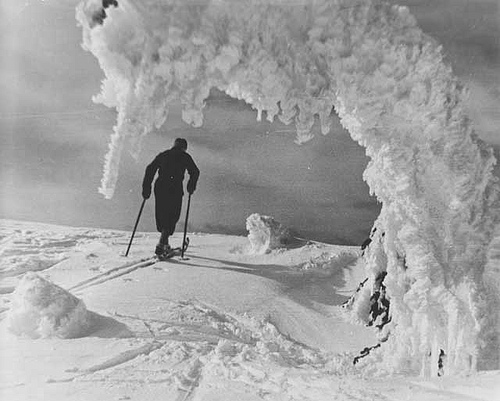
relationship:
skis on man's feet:
[153, 239, 191, 259] [153, 243, 174, 258]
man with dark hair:
[142, 137, 202, 264] [172, 135, 188, 147]